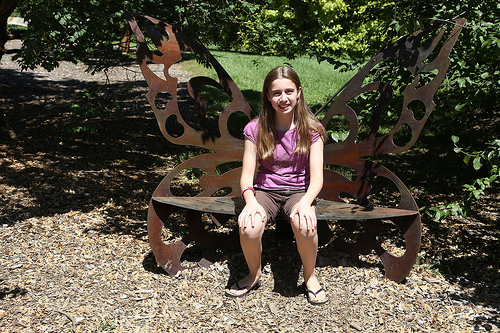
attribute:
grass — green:
[195, 51, 354, 106]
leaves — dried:
[12, 92, 467, 328]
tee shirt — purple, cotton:
[243, 122, 324, 194]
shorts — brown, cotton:
[255, 191, 315, 220]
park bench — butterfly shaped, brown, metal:
[121, 9, 457, 284]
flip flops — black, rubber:
[224, 271, 339, 310]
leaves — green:
[16, 8, 480, 82]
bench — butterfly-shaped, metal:
[124, 6, 469, 285]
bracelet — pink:
[242, 183, 255, 198]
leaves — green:
[430, 176, 484, 219]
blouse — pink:
[246, 120, 321, 201]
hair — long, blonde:
[256, 66, 310, 175]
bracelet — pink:
[242, 184, 252, 195]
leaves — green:
[217, 7, 377, 62]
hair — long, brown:
[258, 64, 307, 161]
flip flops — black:
[225, 273, 327, 304]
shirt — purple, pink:
[243, 114, 323, 190]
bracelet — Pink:
[236, 187, 257, 197]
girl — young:
[222, 63, 330, 305]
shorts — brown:
[250, 188, 315, 222]